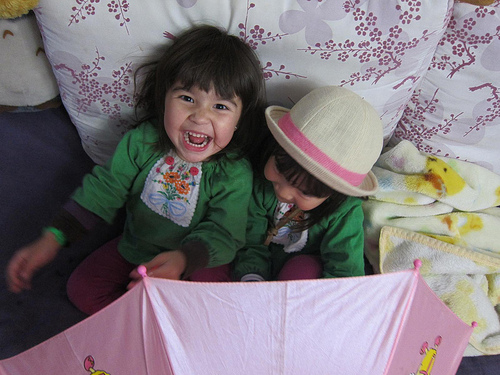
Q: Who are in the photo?
A: Two kids.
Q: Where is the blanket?
A: Behind the girls.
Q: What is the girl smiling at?
A: Camera.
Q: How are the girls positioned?
A: Seated.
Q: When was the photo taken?
A: Daylight.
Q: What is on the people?
A: Matching shirts.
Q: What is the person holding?
A: Umbrella.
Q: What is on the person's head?
A: Hat.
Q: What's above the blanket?
A: Another blanket.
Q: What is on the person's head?
A: Black hair.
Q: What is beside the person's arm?
A: Blue blanket.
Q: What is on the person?
A: Shirt.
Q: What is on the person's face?
A: Smile.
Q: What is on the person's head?
A: Hair.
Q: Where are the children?
A: On the bed.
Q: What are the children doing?
A: Laughing.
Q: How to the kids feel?
A: Happy.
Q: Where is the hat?
A: On the girl.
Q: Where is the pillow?
A: On the bed.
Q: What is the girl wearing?
A: A hat.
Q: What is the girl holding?
A: An umbrella.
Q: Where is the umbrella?
A: In the girl's hands.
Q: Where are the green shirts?
A: On the children.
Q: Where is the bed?
A: Under the children.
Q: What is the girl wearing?
A: A long sleeve green shirt.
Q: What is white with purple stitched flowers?
A: Pillows.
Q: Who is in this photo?
A: A girl with black hair.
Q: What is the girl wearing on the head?
A: A straw hat.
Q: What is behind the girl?
A: A crumpled white and yellow blanket.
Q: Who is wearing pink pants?
A: A girl.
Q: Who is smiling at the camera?
A: A girl with her head on a pillow.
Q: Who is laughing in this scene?
A: Little girl with dark brown hair.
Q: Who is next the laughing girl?
A: Little girl with tan and pink hat.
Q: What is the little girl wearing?
A: A green shirt.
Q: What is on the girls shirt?
A: Flowers.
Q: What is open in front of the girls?
A: Umbrella.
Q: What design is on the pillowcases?
A: Tree.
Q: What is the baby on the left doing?
A: Smiling.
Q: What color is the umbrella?
A: Pink.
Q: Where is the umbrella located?
A: In front of the girls.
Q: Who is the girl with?
A: Another girl in a hat.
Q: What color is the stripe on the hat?
A: Pink.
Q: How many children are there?
A: Two.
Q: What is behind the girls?
A: Blanket.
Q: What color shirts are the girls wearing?
A: Green.